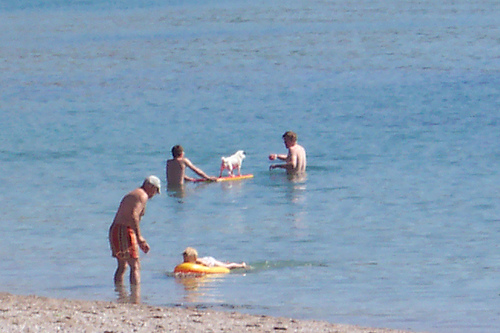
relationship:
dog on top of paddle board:
[216, 145, 243, 175] [195, 161, 256, 190]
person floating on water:
[180, 246, 250, 271] [2, 5, 495, 326]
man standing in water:
[96, 172, 171, 305] [2, 5, 495, 326]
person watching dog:
[267, 127, 309, 181] [216, 145, 243, 175]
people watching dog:
[163, 142, 216, 186] [216, 145, 243, 175]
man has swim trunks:
[96, 172, 171, 305] [103, 222, 147, 263]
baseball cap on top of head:
[143, 171, 169, 193] [139, 173, 167, 199]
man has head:
[96, 172, 171, 305] [139, 173, 167, 199]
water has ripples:
[2, 5, 495, 326] [312, 19, 441, 63]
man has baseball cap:
[96, 172, 171, 305] [143, 175, 165, 192]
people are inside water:
[99, 118, 326, 311] [2, 5, 495, 330]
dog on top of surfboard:
[216, 145, 243, 175] [195, 165, 263, 189]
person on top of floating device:
[180, 246, 250, 271] [173, 260, 232, 278]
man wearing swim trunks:
[96, 172, 171, 305] [105, 222, 147, 262]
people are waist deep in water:
[99, 118, 326, 311] [2, 5, 495, 326]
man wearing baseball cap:
[96, 172, 171, 305] [143, 175, 165, 192]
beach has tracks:
[4, 305, 426, 328] [37, 303, 139, 322]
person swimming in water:
[267, 127, 313, 181] [2, 5, 495, 326]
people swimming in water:
[163, 142, 216, 186] [2, 5, 495, 326]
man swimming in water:
[102, 174, 165, 301] [2, 5, 495, 326]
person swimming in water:
[180, 246, 255, 271] [2, 5, 495, 326]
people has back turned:
[163, 142, 216, 186] [164, 155, 187, 190]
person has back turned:
[267, 127, 313, 181] [290, 146, 311, 182]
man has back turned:
[102, 174, 165, 301] [114, 189, 146, 230]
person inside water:
[267, 127, 309, 181] [2, 5, 495, 326]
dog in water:
[216, 145, 243, 175] [2, 5, 495, 326]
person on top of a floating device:
[180, 246, 255, 271] [173, 256, 232, 279]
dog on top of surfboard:
[216, 145, 243, 175] [203, 171, 253, 185]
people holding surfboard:
[163, 142, 216, 186] [203, 171, 253, 185]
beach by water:
[4, 305, 426, 328] [2, 5, 495, 326]